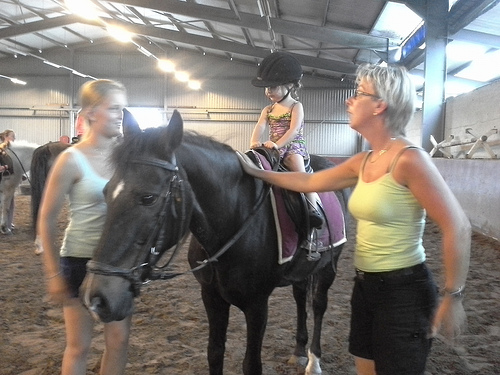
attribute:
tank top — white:
[60, 140, 124, 258]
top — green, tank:
[346, 147, 430, 273]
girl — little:
[233, 47, 337, 270]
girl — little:
[249, 52, 321, 262]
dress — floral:
[263, 100, 310, 169]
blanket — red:
[247, 146, 350, 265]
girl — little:
[249, 45, 326, 152]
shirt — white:
[60, 142, 150, 284]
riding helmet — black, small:
[239, 45, 314, 87]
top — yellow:
[339, 144, 435, 276]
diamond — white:
[106, 174, 127, 199]